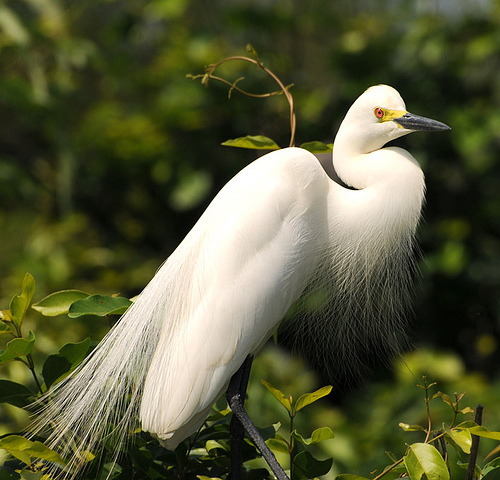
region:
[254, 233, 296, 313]
part of a chest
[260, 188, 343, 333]
part of a chest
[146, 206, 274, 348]
part gof a wing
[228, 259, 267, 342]
part og a wing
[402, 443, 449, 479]
Green leaf on plant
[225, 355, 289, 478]
Long black bird legs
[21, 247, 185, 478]
White wispy tail feathers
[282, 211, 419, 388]
White wisps hanging from neck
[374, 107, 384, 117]
Red eye on a bird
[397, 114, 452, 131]
Long black beak on a bird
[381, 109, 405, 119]
Yellow facial marking in between eye and beak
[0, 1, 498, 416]
Green trees in the background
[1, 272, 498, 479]
Tree leaves and stems underneath bird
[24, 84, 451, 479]
White bird in sun light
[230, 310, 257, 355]
part of a wing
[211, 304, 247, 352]
part of a wing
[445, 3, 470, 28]
this is the sky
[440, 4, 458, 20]
the sky is blue in color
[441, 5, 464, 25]
the sky has clouds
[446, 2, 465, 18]
the clouds are white in color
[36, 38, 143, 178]
this is a tree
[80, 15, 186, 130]
the leaves are small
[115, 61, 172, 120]
the leaves are green in color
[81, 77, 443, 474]
this is a bird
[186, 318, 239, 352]
the feathers are white in color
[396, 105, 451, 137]
this is a beak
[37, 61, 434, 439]
bird on a branch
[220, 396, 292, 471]
branch bird rests on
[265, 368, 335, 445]
twig on a branch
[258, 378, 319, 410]
leaves on a twig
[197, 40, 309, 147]
branch behind bird's head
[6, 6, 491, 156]
trees in the back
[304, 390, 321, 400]
hole in the leaf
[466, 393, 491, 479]
branch near small and medium leaves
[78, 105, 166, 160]
group of leaves on tree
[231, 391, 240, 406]
white knob on branch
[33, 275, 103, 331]
Small green leaves on a tree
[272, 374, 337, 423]
Small green leaves on a tree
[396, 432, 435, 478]
Small green leaves on a tree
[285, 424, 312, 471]
Small green leaves on a tree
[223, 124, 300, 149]
Small green leaves on a tree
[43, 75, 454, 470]
white bird with black beak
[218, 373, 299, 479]
gray legs of the bird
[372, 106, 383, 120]
orange and black eye of the bird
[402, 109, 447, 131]
bird's black beak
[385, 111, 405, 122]
yellow spot on the bird's face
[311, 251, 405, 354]
stray hairs hanging from the bird's chest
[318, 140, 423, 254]
curved neck of the bird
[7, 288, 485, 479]
tree bird is perched in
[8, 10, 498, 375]
trees behind the bird